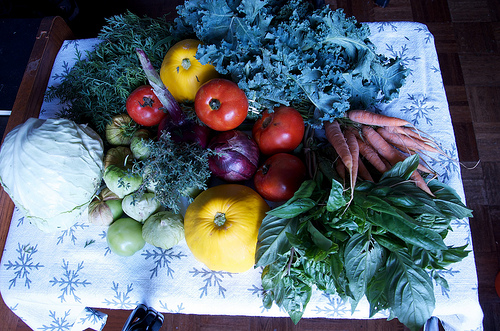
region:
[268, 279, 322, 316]
small bunch of thyme leaves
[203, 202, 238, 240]
top of yellow squash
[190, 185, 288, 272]
large yellow squash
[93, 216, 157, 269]
small green tomato on surface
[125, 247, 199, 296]
small leaf design on plat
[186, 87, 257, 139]
red tomato with stem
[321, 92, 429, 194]
bunches of orange carrots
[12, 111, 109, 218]
stems in green cabbage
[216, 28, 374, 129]
bunches of green kale on plate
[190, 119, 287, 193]
large purple onion on the surface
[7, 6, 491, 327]
vegetables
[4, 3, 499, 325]
a bunch of vegetables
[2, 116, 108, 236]
a green head of lettuce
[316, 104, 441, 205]
a cluster of carrots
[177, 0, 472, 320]
dark leafy greens are on the table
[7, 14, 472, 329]
a cloth covers the table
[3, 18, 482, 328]
the cloth is white with blue designs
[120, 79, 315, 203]
four tomatoes are in the group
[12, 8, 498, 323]
the white cloth wrapped around a board which is on a table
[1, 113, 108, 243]
a cabbage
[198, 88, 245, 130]
this is a tomato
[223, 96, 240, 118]
the tomato is red in color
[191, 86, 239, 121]
the tomato is round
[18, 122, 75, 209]
this is a cabbage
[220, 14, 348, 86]
this is a vegetable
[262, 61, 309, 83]
the vegetable is green in color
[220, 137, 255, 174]
this is an onion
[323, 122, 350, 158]
this is a carrot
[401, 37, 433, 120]
this is a table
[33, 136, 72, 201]
the cabbage is fresh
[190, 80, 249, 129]
Tomato under the leaf lettuce.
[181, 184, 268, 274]
Large yellow squash on the bottom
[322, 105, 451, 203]
Group of carrots on the right.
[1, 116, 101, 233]
A green head of cabbage.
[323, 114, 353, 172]
Orange carrot close to a tomato.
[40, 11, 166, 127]
A pile of Rosemary to the upper left of a tomato.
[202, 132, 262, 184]
Large red onion in the center of the pile.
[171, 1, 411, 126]
Large pile of leaf lettuce at the top.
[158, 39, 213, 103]
Small yellow squash at the top.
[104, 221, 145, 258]
Green tomato on the bottom.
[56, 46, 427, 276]
pile of vegetables on table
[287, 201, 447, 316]
green leaves of vegetable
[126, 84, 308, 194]
four red tomatoes on pile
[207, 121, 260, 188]
purple skin of onion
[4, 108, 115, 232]
head of cabbage near edge of table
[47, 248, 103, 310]
snowflake design on tablecloth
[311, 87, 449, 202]
bunch of carrots on right side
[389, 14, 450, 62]
corner of table cloth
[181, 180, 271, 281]
large yellow vegetable on table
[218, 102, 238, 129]
light reflection on tomato